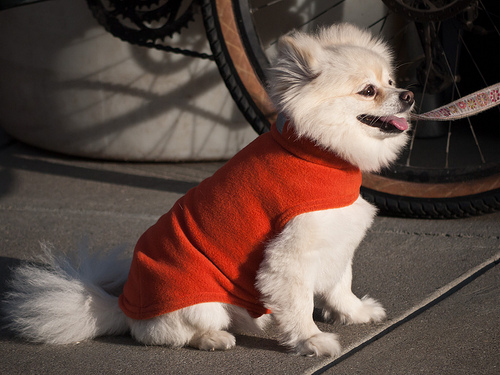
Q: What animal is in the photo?
A: A dog.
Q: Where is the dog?
A: On the sidewalk.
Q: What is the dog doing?
A: Sitting down.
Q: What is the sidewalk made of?
A: Concrete.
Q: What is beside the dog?
A: A bicycle tire.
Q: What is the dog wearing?
A: A sweater.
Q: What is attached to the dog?
A: A leash.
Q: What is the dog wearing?
A: A red coat.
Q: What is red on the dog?
A: The coat.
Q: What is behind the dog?
A: A bicycle tire.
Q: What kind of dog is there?
A: A pomeranian.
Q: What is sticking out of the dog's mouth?
A: The tongue.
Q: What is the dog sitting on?
A: The sidewalk.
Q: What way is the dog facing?
A: To the right.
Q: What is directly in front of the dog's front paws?
A: A line in the sidewalk.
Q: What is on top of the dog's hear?
A: Ears.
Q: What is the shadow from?
A: Wheel.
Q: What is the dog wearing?
A: Red weater.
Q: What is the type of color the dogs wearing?
A: Red.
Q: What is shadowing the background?
A: Wheel.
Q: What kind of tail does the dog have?
A: Fluffy.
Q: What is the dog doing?
A: Sitting.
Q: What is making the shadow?
A: Bike wheel.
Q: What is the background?
A: Wheel shadow.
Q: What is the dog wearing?
A: Sweater.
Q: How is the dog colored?
A: White.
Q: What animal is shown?
A: A dog.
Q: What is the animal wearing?
A: A red coat.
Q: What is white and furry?
A: A dog.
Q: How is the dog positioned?
A: Sitting.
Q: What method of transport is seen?
A: A bicycle.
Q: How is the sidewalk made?
A: Of concrete.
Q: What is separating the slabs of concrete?
A: A crack.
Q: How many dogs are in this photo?
A: One.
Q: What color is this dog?
A: White.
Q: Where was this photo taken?
A: Near a dog in a jacket.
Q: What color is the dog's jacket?
A: Orange.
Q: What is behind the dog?
A: A bicycle.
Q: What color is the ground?
A: Gray.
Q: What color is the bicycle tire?
A: Black.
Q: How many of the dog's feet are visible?
A: Three.